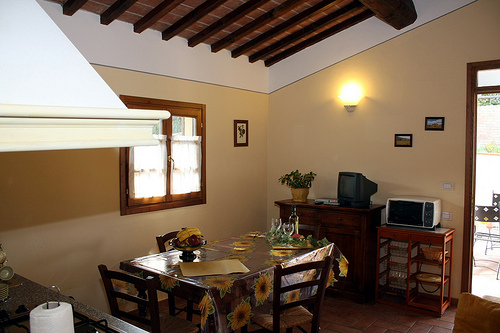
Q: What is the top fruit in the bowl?
A: Banana.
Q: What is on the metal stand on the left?
A: Paper towels.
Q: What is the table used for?
A: Dining.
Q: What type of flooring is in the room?
A: Tile.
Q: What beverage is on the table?
A: Wine.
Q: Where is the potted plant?
A: Next to the television.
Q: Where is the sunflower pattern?
A: On the tablecloth.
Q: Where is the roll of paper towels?
A: Near the stove.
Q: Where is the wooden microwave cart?
A: Near the glass door.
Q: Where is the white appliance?
A: Next to the television.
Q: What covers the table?
A: A tablecloth.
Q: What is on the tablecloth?
A: Flowers.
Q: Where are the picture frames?
A: On the wall.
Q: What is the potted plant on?
A: A storage cabinet.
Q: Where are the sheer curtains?
A: Over the windows.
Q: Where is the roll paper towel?
A: The paper towel holder.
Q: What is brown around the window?
A: The window frame.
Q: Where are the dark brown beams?
A: On the ceiling.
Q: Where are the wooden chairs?
A: Around the table.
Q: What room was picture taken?
A: Dining.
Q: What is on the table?
A: Tablecloth.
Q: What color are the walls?
A: Tan.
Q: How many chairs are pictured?
A: 3.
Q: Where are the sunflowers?
A: Tablecloth.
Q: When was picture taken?
A: Daytime.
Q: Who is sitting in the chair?
A: Nobody.